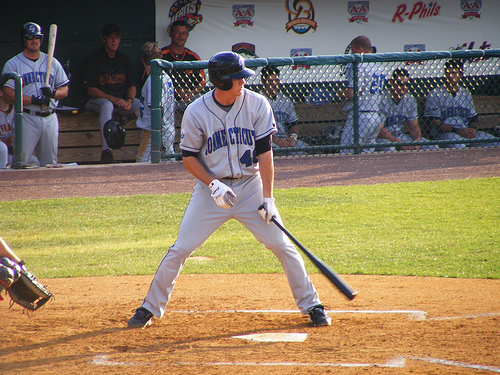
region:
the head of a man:
[186, 37, 286, 107]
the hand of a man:
[208, 169, 245, 210]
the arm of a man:
[160, 102, 235, 207]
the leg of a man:
[125, 199, 235, 328]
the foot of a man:
[112, 287, 159, 347]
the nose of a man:
[231, 75, 249, 93]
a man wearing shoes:
[102, 287, 194, 341]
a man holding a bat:
[213, 54, 438, 315]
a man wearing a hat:
[191, 26, 279, 108]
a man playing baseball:
[100, 1, 425, 368]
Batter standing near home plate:
[128, 50, 354, 326]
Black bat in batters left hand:
[256, 201, 357, 298]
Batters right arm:
[176, 100, 238, 209]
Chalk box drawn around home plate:
[95, 293, 430, 372]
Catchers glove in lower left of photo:
[6, 258, 53, 315]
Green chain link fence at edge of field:
[146, 44, 498, 150]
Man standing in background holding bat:
[8, 18, 73, 164]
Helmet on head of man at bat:
[208, 48, 255, 95]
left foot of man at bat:
[301, 293, 334, 333]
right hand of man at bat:
[208, 173, 233, 210]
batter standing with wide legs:
[121, 47, 333, 335]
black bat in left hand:
[253, 195, 360, 300]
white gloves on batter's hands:
[207, 177, 278, 222]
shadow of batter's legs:
[0, 316, 316, 371]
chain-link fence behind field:
[150, 46, 498, 149]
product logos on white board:
[153, 1, 498, 78]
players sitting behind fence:
[253, 58, 495, 156]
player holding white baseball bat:
[2, 19, 73, 166]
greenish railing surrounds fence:
[143, 46, 498, 163]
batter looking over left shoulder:
[201, 48, 258, 107]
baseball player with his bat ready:
[136, 51, 362, 325]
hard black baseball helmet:
[199, 49, 255, 88]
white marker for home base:
[233, 323, 307, 345]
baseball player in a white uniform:
[136, 49, 334, 327]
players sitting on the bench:
[256, 52, 483, 157]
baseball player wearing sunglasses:
[20, 22, 42, 56]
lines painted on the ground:
[84, 346, 219, 373]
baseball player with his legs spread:
[131, 51, 334, 324]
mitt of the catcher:
[4, 266, 50, 311]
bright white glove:
[207, 179, 235, 210]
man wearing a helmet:
[110, 35, 356, 322]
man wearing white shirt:
[125, 51, 340, 322]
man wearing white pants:
[125, 40, 340, 330]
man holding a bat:
[121, 45, 346, 325]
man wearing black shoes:
[125, 50, 355, 325]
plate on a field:
[221, 320, 316, 350]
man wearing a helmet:
[15, 10, 65, 156]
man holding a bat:
[15, 20, 80, 165]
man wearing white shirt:
[5, 10, 62, 160]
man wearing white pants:
[3, 14, 70, 163]